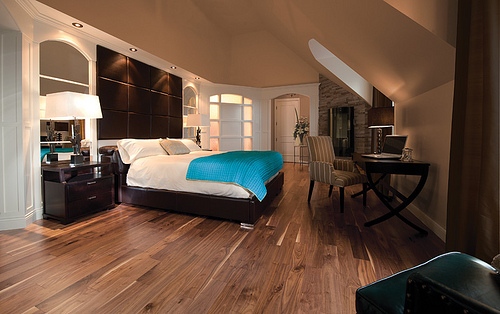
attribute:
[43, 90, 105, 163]
lamp — table, nice looking, nice, beautiful, tall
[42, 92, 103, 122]
shade — rectangular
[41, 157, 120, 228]
nightstand — wooden, large, dark, stained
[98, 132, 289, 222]
bed — queen size, king size, wood, king sized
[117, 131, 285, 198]
linens — white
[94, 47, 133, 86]
rectangle — wooden, mounted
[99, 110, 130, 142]
rectangle — wooden, mounted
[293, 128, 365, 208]
chair — striped, wooden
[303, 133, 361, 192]
upholstery — striped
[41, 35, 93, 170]
mirror — glass, shiny, tall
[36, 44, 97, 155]
shape — arch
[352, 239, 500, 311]
chair — leather, brown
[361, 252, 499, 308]
leather — green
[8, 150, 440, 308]
floor — oak, hardwood, stained, wood, comprised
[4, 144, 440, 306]
planks — long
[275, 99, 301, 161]
door — white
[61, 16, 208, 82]
lighting — track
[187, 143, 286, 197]
bedspread — blue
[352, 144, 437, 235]
table — wooden, long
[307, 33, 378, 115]
skylight — here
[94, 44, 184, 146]
hanging — brown, decorative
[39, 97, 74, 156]
reflection — lamp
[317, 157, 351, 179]
cushion — striped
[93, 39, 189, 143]
decoration — wall, large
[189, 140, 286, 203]
sheet — light, blue, bed, light blue